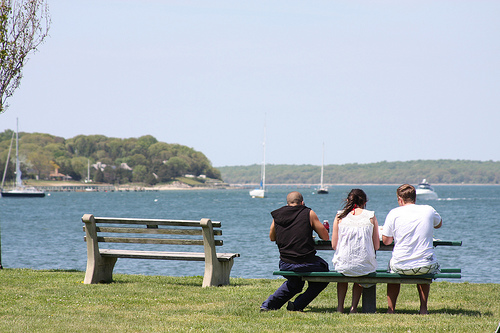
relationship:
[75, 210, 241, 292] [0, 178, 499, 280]
bench overlooking water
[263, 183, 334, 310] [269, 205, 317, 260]
man in black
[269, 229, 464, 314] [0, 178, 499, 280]
table near water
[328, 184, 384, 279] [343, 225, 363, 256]
lady in white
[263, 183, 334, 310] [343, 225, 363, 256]
man in white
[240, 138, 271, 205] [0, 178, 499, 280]
sailboat on water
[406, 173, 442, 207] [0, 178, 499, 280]
motorboat on water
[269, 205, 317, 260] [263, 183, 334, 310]
black on man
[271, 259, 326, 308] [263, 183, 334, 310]
pants on man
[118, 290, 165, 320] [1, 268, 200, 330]
grass on bank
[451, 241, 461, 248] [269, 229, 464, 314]
green picnic table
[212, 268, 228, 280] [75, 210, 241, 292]
gray park bench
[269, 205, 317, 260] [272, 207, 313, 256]
black tank top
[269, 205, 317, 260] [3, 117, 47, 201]
black white boat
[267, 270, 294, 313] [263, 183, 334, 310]
leg of man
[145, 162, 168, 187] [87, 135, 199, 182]
section of trees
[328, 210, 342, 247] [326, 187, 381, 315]
arm of lady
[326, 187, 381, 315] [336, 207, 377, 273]
lady sleeveless shirt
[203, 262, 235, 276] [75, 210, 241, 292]
cement park bench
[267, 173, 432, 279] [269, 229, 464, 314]
people at table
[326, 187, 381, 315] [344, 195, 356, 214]
lady with hair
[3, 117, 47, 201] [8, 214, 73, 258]
boat in water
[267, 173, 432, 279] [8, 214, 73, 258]
people at water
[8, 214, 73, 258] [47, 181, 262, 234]
water in harbor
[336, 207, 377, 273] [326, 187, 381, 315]
shirt by lady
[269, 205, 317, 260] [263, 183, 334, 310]
black by man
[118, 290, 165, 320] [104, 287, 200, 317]
grass on ground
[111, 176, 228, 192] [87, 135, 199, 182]
shoreline in trees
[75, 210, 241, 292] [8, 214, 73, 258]
bench by water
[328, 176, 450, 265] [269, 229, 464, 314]
friends at table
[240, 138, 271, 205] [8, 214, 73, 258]
sailboat in water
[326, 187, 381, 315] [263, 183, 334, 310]
lady and man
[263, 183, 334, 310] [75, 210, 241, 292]
man on bench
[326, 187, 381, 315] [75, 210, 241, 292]
lady on bench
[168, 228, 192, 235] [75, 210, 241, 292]
wooden park bench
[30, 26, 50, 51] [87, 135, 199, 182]
branches on trees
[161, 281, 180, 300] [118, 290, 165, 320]
short green grass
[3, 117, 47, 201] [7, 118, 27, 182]
boat with mast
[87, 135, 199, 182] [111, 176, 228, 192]
trees on shoreline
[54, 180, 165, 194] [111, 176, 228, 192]
dock at shoreline